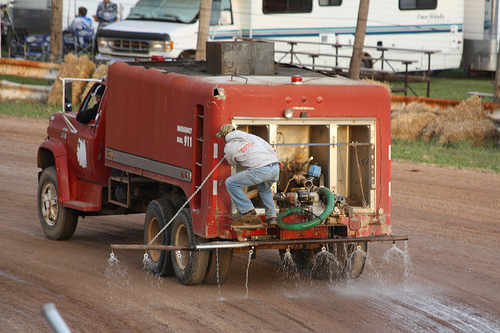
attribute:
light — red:
[290, 71, 305, 86]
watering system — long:
[187, 229, 399, 261]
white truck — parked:
[90, 0, 467, 78]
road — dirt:
[15, 109, 490, 300]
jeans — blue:
[221, 161, 285, 212]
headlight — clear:
[145, 41, 170, 55]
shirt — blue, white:
[221, 129, 281, 169]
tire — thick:
[34, 166, 77, 242]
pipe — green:
[274, 187, 336, 229]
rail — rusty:
[304, 32, 496, 143]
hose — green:
[278, 191, 332, 231]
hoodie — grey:
[219, 133, 276, 171]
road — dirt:
[280, 270, 487, 331]